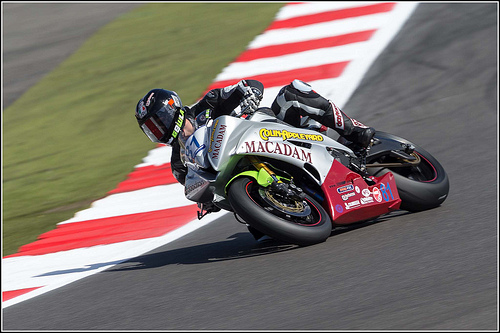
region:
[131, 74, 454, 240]
man racing a motorcycle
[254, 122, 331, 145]
yellow lettering with black outline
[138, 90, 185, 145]
black helmet with visor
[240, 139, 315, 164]
dark red lettering on silver background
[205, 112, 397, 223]
silver and red body of the motorbike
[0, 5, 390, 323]
red and white striping next to track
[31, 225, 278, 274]
shadow of the motorbike and racer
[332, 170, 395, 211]
stickers on the motorbike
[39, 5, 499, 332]
track the man is racing on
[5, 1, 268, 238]
strip of grass next to red and white border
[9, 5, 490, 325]
a scene outside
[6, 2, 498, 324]
a scene at a race track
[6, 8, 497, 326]
a scene during the day time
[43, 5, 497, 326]
a gray pavement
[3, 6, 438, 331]
a red and white boundary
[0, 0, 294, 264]
a patch of grass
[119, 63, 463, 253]
a black and gray motorcycle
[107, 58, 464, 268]
a person on a bike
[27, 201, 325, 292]
a shadow on the ground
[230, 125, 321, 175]
word MACADAM on the bike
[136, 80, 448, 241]
person racing on a motorcycle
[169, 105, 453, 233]
silver and maroon bike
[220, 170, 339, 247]
thin smooth tire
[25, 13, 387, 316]
red and white stripes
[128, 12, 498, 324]
dark grey race track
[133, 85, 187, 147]
black helmet with yellow lettering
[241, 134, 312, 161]
maroon word on bike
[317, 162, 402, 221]
numerous logos on the bike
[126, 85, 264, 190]
racer wearing a black suit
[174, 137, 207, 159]
blue numbers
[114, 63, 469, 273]
person on a motorized bike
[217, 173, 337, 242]
front tire on the bike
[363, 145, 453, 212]
rear tire on the bike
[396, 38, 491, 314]
pavement bike rides on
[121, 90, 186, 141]
helmet on the rider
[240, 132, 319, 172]
name on the bike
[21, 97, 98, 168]
green space on the ground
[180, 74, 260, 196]
jacket on the rider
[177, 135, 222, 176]
number on the bike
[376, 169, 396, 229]
number on the bike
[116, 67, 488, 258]
a man on a motorcycle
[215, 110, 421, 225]
a gray and red motorcycle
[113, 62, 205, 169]
a black helmet on head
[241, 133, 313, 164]
red letters on bike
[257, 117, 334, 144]
yellow letters on bike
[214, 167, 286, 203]
green around the wheel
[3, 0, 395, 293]
a long red and white strip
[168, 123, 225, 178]
81 on the bike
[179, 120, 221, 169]
blue number on the bike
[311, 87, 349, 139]
red letters on the leg